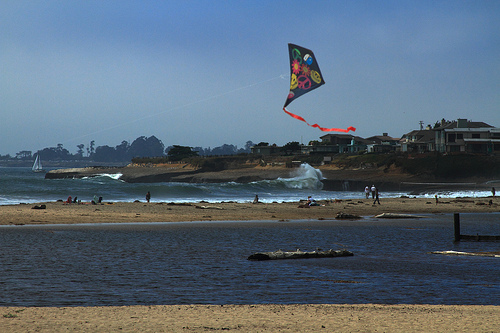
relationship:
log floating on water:
[239, 245, 355, 265] [3, 218, 500, 304]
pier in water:
[40, 162, 135, 178] [7, 161, 478, 198]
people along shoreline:
[358, 183, 388, 210] [0, 186, 498, 220]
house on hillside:
[318, 127, 366, 151] [216, 113, 498, 172]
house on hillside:
[362, 130, 406, 154] [216, 113, 498, 172]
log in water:
[239, 245, 355, 265] [3, 218, 500, 304]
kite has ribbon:
[284, 43, 324, 110] [286, 107, 355, 141]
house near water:
[318, 127, 366, 151] [7, 161, 478, 198]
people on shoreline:
[61, 193, 109, 209] [0, 186, 498, 220]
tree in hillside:
[278, 139, 305, 153] [216, 113, 498, 172]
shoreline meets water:
[0, 186, 498, 220] [3, 218, 500, 304]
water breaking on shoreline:
[7, 161, 478, 198] [0, 186, 498, 220]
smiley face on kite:
[309, 70, 325, 87] [284, 43, 324, 110]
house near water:
[318, 127, 366, 151] [3, 218, 500, 304]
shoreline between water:
[0, 186, 498, 220] [7, 161, 478, 198]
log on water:
[239, 245, 355, 265] [3, 218, 500, 304]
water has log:
[3, 218, 500, 304] [239, 245, 355, 265]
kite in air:
[284, 43, 324, 110] [18, 6, 266, 131]